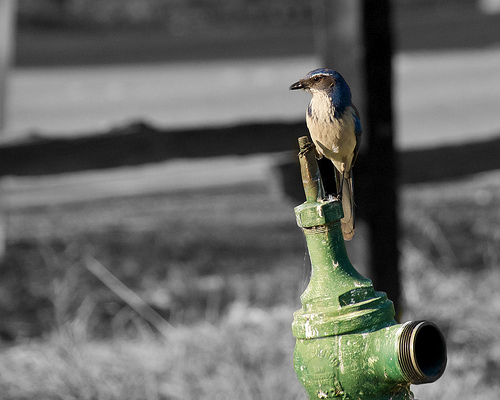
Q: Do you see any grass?
A: Yes, there is grass.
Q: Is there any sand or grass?
A: Yes, there is grass.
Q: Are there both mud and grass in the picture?
A: No, there is grass but no mud.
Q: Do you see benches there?
A: No, there are no benches.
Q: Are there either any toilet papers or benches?
A: No, there are no benches or toilet papers.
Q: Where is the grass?
A: The grass is on the ground.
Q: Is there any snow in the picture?
A: Yes, there is snow.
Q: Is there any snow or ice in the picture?
A: Yes, there is snow.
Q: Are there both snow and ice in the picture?
A: No, there is snow but no ice.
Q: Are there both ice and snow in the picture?
A: No, there is snow but no ice.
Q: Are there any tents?
A: No, there are no tents.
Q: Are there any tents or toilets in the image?
A: No, there are no tents or toilets.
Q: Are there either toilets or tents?
A: No, there are no tents or toilets.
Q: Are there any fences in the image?
A: Yes, there is a fence.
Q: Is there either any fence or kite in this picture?
A: Yes, there is a fence.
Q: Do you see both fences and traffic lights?
A: No, there is a fence but no traffic lights.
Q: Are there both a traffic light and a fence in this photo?
A: No, there is a fence but no traffic lights.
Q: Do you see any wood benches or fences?
A: Yes, there is a wood fence.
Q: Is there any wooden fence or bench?
A: Yes, there is a wood fence.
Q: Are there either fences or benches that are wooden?
A: Yes, the fence is wooden.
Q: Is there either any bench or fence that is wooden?
A: Yes, the fence is wooden.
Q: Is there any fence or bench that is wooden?
A: Yes, the fence is wooden.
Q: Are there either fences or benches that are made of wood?
A: Yes, the fence is made of wood.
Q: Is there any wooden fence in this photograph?
A: Yes, there is a wood fence.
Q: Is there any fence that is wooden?
A: Yes, there is a fence that is wooden.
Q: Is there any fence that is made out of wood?
A: Yes, there is a fence that is made of wood.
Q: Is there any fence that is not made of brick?
A: Yes, there is a fence that is made of wood.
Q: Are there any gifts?
A: No, there are no gifts.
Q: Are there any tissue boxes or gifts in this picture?
A: No, there are no gifts or tissue boxes.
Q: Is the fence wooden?
A: Yes, the fence is wooden.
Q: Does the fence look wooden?
A: Yes, the fence is wooden.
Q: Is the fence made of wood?
A: Yes, the fence is made of wood.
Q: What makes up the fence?
A: The fence is made of wood.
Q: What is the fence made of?
A: The fence is made of wood.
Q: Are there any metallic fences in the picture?
A: No, there is a fence but it is wooden.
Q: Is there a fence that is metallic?
A: No, there is a fence but it is wooden.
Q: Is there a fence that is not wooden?
A: No, there is a fence but it is wooden.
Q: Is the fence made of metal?
A: No, the fence is made of wood.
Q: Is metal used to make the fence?
A: No, the fence is made of wood.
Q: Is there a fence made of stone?
A: No, there is a fence but it is made of wood.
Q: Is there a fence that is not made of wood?
A: No, there is a fence but it is made of wood.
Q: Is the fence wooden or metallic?
A: The fence is wooden.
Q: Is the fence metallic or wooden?
A: The fence is wooden.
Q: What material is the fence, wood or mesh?
A: The fence is made of wood.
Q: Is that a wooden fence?
A: Yes, that is a wooden fence.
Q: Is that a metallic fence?
A: No, that is a wooden fence.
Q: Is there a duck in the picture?
A: No, there are no ducks.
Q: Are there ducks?
A: No, there are no ducks.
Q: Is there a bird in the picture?
A: Yes, there is a bird.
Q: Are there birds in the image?
A: Yes, there is a bird.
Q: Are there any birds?
A: Yes, there is a bird.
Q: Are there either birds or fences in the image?
A: Yes, there is a bird.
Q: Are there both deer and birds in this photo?
A: No, there is a bird but no deer.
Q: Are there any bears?
A: No, there are no bears.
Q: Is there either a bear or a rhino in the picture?
A: No, there are no bears or rhinos.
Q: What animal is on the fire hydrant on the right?
A: The bird is on the hydrant.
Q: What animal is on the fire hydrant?
A: The bird is on the hydrant.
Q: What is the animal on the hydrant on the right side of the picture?
A: The animal is a bird.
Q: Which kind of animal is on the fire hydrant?
A: The animal is a bird.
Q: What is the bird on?
A: The bird is on the fire hydrant.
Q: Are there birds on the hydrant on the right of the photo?
A: Yes, there is a bird on the fire hydrant.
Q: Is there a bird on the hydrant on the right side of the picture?
A: Yes, there is a bird on the fire hydrant.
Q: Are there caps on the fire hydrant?
A: No, there is a bird on the fire hydrant.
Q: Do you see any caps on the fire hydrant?
A: No, there is a bird on the fire hydrant.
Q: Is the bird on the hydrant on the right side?
A: Yes, the bird is on the fire hydrant.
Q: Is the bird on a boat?
A: No, the bird is on the fire hydrant.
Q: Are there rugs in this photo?
A: No, there are no rugs.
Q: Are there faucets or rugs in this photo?
A: No, there are no rugs or faucets.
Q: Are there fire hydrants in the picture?
A: Yes, there is a fire hydrant.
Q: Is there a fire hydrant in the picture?
A: Yes, there is a fire hydrant.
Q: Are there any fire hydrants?
A: Yes, there is a fire hydrant.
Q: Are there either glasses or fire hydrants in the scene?
A: Yes, there is a fire hydrant.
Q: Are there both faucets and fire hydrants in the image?
A: No, there is a fire hydrant but no faucets.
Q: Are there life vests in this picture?
A: No, there are no life vests.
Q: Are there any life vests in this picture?
A: No, there are no life vests.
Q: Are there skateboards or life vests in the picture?
A: No, there are no life vests or skateboards.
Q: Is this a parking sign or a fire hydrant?
A: This is a fire hydrant.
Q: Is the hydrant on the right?
A: Yes, the hydrant is on the right of the image.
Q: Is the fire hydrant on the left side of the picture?
A: No, the fire hydrant is on the right of the image.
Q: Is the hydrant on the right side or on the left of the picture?
A: The hydrant is on the right of the image.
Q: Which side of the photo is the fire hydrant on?
A: The fire hydrant is on the right of the image.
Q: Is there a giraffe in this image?
A: No, there are no giraffes.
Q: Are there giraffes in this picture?
A: No, there are no giraffes.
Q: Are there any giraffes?
A: No, there are no giraffes.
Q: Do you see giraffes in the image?
A: No, there are no giraffes.